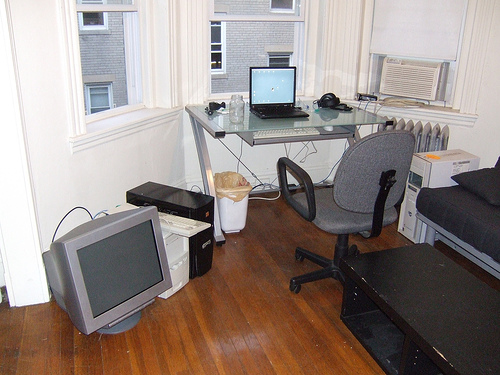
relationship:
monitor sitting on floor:
[41, 203, 172, 335] [0, 189, 397, 375]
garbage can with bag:
[214, 167, 251, 239] [213, 167, 251, 191]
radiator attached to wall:
[375, 116, 451, 159] [366, 91, 496, 141]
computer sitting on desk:
[249, 65, 309, 120] [178, 93, 397, 243]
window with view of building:
[70, 8, 155, 126] [89, 25, 126, 98]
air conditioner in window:
[378, 59, 448, 102] [355, 0, 469, 112]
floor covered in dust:
[0, 189, 397, 375] [0, 195, 412, 372]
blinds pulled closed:
[361, 7, 473, 95] [358, 24, 477, 76]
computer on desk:
[242, 60, 317, 137] [185, 101, 395, 141]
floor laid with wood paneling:
[13, 189, 398, 372] [209, 286, 275, 353]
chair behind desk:
[280, 142, 419, 234] [263, 125, 417, 255]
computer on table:
[249, 65, 309, 120] [202, 101, 397, 134]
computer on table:
[249, 65, 309, 120] [339, 247, 495, 367]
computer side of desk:
[405, 139, 493, 221] [178, 93, 397, 243]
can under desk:
[211, 167, 253, 239] [184, 97, 389, 241]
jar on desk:
[227, 94, 245, 124] [178, 93, 397, 243]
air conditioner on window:
[378, 57, 448, 102] [352, 0, 482, 102]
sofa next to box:
[393, 158, 498, 239] [336, 230, 497, 371]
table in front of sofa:
[328, 249, 492, 369] [409, 162, 499, 287]